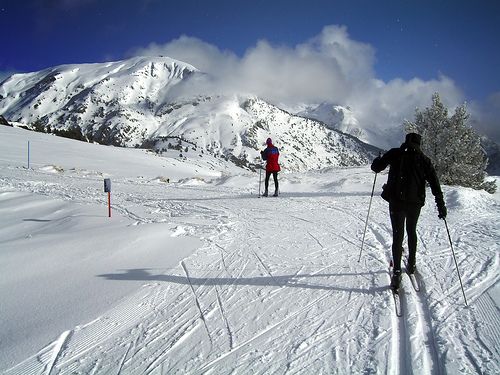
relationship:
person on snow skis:
[372, 131, 448, 256] [389, 254, 420, 318]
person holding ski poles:
[372, 131, 448, 256] [366, 169, 467, 307]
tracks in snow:
[365, 218, 443, 372] [2, 125, 496, 371]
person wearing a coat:
[255, 141, 280, 193] [261, 144, 281, 175]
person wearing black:
[372, 131, 448, 256] [378, 146, 441, 259]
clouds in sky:
[137, 27, 496, 149] [0, 3, 499, 148]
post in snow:
[101, 177, 119, 217] [2, 125, 496, 371]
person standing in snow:
[372, 131, 448, 256] [2, 125, 496, 371]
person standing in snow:
[255, 141, 280, 193] [2, 125, 496, 371]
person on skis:
[255, 141, 280, 193] [261, 189, 278, 198]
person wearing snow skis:
[372, 131, 448, 256] [389, 254, 420, 318]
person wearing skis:
[255, 141, 280, 193] [261, 189, 278, 198]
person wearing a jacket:
[372, 131, 448, 256] [376, 148, 441, 202]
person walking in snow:
[255, 141, 280, 193] [2, 125, 496, 371]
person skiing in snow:
[372, 131, 448, 256] [2, 125, 496, 371]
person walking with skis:
[255, 141, 280, 193] [261, 189, 278, 198]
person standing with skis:
[255, 141, 280, 193] [261, 189, 278, 198]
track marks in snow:
[34, 159, 496, 370] [2, 125, 496, 371]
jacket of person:
[376, 148, 441, 202] [372, 131, 448, 256]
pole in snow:
[24, 143, 35, 171] [2, 125, 496, 371]